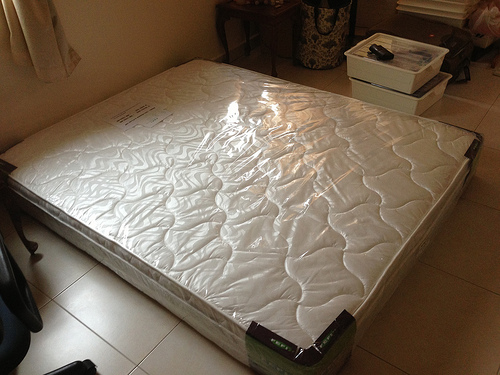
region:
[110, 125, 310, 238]
one new bed is seen.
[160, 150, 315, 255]
bed is white color.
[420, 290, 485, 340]
floor is white color.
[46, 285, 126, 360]
floor made of tiles.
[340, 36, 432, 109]
two boxes on floor.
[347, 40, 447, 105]
box is white color.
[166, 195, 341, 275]
bed is white color.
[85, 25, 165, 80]
wall is brown color.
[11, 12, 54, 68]
screen is brown color.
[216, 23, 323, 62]
table is brown color.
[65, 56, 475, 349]
large white mattress laying on floor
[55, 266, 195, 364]
tiles on floor are large and white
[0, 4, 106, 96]
drapery or towel hanging down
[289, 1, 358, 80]
colorful design purse or bag in the distance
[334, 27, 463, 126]
two white bins sitting on top of each other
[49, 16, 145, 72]
tan wall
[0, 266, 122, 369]
items in the foreground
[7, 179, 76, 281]
leg of small table or chair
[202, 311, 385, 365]
four edges protectors on matress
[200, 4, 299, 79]
small dark colored table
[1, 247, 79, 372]
this is a chair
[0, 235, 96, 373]
the chair arms is black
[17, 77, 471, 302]
this is a mattress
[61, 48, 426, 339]
the mattress is rectangle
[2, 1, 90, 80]
this is a curtain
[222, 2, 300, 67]
these is a stool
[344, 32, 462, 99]
these are trays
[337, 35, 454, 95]
the tray is cream in color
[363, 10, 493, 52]
this is a bag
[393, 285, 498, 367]
this is afloor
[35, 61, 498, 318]
mattress covered in plastic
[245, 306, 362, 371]
black cardboard on mattress corner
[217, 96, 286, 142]
light reflection on plastic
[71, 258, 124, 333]
tile floor under mattress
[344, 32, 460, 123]
two containers on floor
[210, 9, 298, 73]
table legs next to mattress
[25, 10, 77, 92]
window curtain above mattress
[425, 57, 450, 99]
two handles on containers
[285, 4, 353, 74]
bag with handle on floor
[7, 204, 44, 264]
wood leg on floor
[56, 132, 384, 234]
this is a matress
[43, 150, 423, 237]
the matress is white in color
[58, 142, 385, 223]
the matress is large in size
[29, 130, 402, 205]
the matress is flat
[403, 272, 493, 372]
the floor is tiled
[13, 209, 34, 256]
this is a stools leg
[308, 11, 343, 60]
this is a hand bag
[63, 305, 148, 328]
the floor is white in color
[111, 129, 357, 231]
the matress is comfy